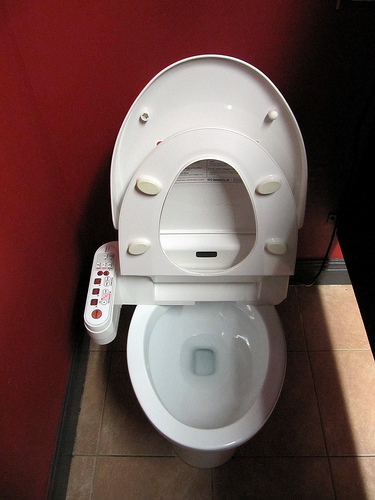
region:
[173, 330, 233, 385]
Water in a toilet.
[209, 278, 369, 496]
A shadow in a bathroom stall.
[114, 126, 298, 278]
A toilet seat that is raised up.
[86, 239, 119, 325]
A control panel on a toilet.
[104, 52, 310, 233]
The lid of a toilet.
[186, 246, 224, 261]
A sensor on a toilet.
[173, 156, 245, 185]
Text on the underside of a toilet lid.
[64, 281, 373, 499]
Tan tiles on the floor.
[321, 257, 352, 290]
A piece of black border in the bathroom.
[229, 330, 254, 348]
A reflection of light in a toilet.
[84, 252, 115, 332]
buttons on the side of the toliet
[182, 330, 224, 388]
water in the toliet bowl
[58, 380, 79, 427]
black board near wall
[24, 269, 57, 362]
red wall next to the toliet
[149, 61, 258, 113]
cover of the toliet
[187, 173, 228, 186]
direction sticker on the back of the toliet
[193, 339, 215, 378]
hole that waste goes down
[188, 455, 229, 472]
bottom of the toliet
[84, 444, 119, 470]
lines on the floor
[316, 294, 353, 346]
shadow on the floor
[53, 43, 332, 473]
a toilet in a restroom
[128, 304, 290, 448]
the bowl of a toilet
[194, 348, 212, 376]
the drain of a toilet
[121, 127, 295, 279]
the seat of a toilet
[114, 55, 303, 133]
the lid of a toilet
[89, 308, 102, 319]
a button on the arm of a toilet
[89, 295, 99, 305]
a button on the arm of a toilet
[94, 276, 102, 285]
a button on the arm of a toilet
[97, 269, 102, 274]
a button on the arm of a toilet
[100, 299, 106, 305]
a button on the arm of a toilet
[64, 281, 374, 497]
tile on bathroom floor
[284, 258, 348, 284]
brown baseboard in bathroom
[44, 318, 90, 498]
brown baseboard in bathroom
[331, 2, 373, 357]
bathroom stall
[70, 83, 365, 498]
shadow from bathroom stall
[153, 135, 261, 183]
label on toilet seat lid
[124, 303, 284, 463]
white ceramic toilet bowl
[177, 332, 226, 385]
water in toilet bowl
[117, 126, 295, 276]
white plastic toilet seat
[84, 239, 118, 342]
control panel on toilet